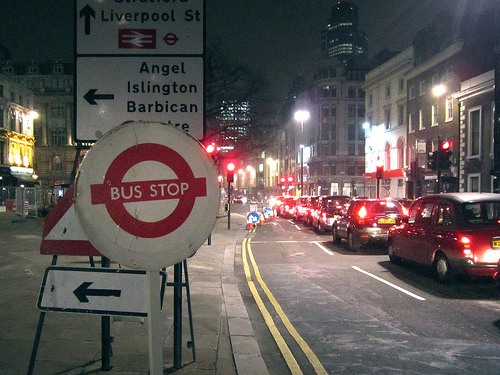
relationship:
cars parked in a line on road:
[346, 165, 496, 289] [247, 160, 494, 323]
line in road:
[358, 263, 422, 309] [0, 201, 500, 373]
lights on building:
[361, 121, 391, 171] [359, 63, 413, 183]